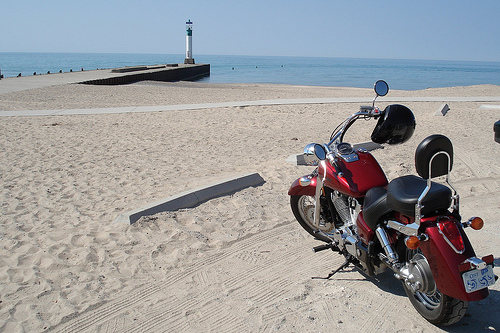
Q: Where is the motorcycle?
A: Beach.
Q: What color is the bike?
A: Red.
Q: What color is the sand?
A: Tan.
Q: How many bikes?
A: One.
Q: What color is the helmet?
A: Black.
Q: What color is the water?
A: Blue.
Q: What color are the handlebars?
A: Silver.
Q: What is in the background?
A: Water.